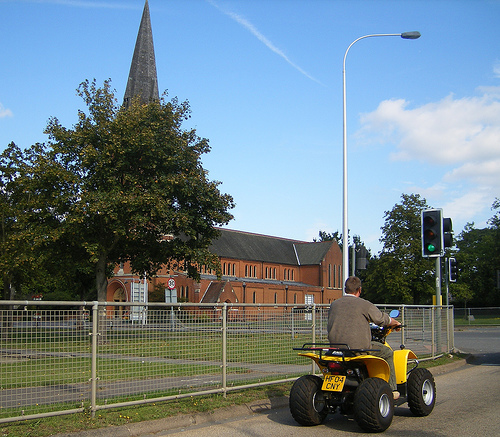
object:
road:
[123, 326, 500, 436]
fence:
[0, 296, 455, 425]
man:
[324, 267, 401, 401]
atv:
[289, 301, 438, 433]